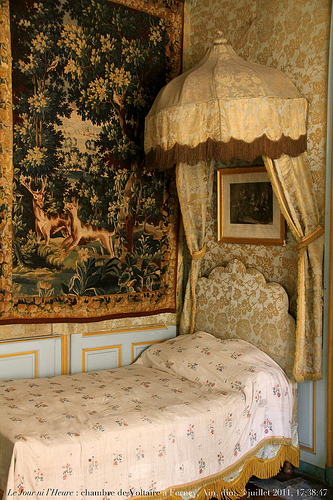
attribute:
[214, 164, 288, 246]
photo — gold framed, framed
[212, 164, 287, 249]
frame — gold, silver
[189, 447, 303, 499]
fringe — mustard yellow, yellow, brown, decorative, gold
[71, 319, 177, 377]
wall — yellow, white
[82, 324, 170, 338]
edge — yellow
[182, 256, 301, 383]
headboard — silken, floral, yellow, cloth, gold, fabric, white, patterned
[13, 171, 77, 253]
buck — embroidered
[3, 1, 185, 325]
tapestry — hand embroidered, large, deer themed, hanging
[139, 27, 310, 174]
feature — decorative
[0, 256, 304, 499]
bed — gold color, floral design, single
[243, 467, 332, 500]
floor — hardwood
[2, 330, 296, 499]
bed spread — floral, cream colored, flowered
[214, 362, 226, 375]
flower — small, red, blue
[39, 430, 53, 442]
flower — red, blue, small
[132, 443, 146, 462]
flower — red, blue, small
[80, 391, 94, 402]
flower — small, red, blue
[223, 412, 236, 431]
flower — small, red, blue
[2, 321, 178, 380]
wainscoating — yellow, white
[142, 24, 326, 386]
canopy — decorative, tapestry, gold, fabric, white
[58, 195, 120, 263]
deer — embroidered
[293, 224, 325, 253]
tie back — gold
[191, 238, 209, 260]
tie back — gold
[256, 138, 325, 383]
curtain — fabric, gold, white, floral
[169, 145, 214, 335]
curtain — gold, fabric, white, floral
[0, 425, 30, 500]
foot — wood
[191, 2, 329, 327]
wallpaper — gold, floral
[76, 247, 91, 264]
flower — red, white